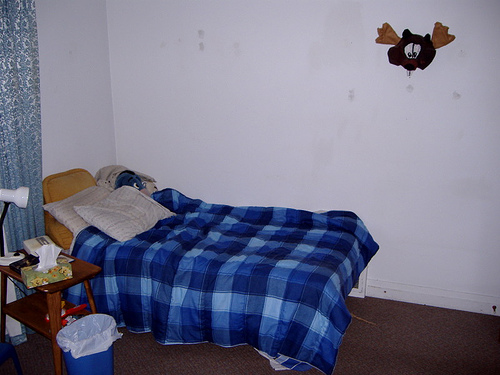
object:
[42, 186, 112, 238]
pillow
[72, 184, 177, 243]
bed pillow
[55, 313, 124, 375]
garbage can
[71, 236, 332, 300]
edge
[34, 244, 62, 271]
tissues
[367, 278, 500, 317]
trim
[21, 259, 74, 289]
box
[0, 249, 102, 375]
night stand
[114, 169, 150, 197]
doll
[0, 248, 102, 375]
table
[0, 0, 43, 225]
window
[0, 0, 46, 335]
curtain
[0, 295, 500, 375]
brown carpet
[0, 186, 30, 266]
lamp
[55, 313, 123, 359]
trash bag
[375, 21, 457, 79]
character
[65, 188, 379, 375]
blue comforter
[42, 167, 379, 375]
bed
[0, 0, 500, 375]
bedroom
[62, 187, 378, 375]
spread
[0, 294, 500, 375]
floor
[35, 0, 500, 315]
walls